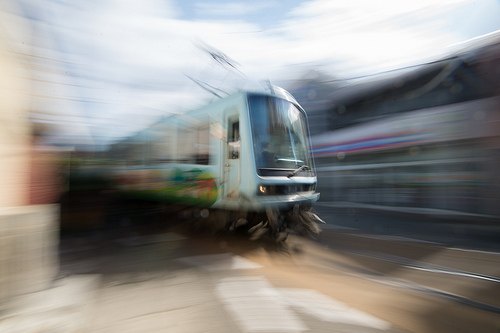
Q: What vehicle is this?
A: A train.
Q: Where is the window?
A: On the train.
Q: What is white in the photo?
A: Clouds.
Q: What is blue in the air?
A: The sky.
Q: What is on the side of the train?
A: Windows.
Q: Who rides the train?
A: Passengers.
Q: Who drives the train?
A: An engineer.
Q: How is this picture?
A: Blurry.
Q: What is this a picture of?
A: Train.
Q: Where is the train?
A: Train tracks.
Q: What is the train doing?
A: Moving.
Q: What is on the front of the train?
A: Large window.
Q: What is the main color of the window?
A: Black.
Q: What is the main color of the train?
A: White.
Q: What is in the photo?
A: A train.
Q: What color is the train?
A: White.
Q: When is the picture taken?
A: During the day.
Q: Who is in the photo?
A: No one.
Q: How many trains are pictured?
A: One.